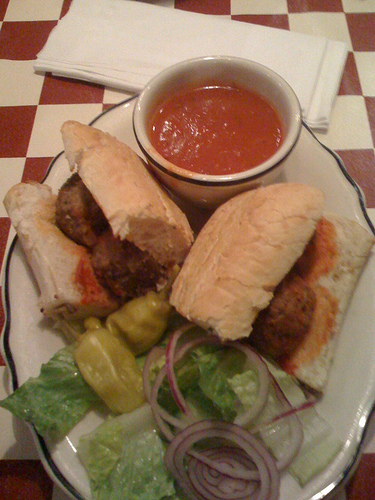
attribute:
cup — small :
[130, 54, 306, 213]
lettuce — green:
[0, 333, 346, 499]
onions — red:
[165, 410, 276, 497]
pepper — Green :
[104, 277, 172, 356]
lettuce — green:
[1, 345, 105, 452]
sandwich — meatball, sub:
[186, 180, 365, 395]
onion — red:
[144, 325, 306, 498]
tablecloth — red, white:
[30, 71, 54, 164]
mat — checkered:
[5, 40, 77, 174]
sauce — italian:
[172, 86, 241, 157]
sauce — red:
[150, 80, 282, 175]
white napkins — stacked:
[59, 9, 204, 60]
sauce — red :
[321, 252, 334, 278]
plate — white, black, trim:
[2, 84, 373, 497]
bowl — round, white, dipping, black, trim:
[139, 44, 285, 181]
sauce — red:
[137, 73, 286, 186]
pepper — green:
[66, 322, 146, 415]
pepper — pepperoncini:
[50, 317, 146, 412]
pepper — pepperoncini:
[104, 263, 181, 356]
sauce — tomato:
[185, 89, 247, 153]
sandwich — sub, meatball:
[200, 212, 363, 351]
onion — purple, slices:
[158, 330, 295, 493]